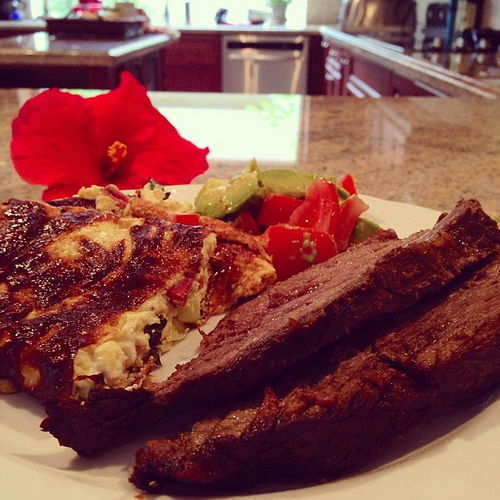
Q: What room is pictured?
A: It is a kitchen.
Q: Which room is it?
A: It is a kitchen.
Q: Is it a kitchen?
A: Yes, it is a kitchen.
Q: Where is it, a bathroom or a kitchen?
A: It is a kitchen.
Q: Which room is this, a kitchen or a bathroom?
A: It is a kitchen.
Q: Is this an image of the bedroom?
A: No, the picture is showing the kitchen.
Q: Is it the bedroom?
A: No, it is the kitchen.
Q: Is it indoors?
A: Yes, it is indoors.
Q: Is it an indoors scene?
A: Yes, it is indoors.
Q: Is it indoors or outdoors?
A: It is indoors.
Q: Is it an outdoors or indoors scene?
A: It is indoors.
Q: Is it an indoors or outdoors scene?
A: It is indoors.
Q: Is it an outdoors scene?
A: No, it is indoors.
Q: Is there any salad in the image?
A: Yes, there is salad.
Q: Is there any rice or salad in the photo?
A: Yes, there is salad.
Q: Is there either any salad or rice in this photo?
A: Yes, there is salad.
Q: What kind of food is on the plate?
A: The food is salad.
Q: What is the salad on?
A: The salad is on the plate.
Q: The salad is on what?
A: The salad is on the plate.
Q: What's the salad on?
A: The salad is on the plate.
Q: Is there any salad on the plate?
A: Yes, there is salad on the plate.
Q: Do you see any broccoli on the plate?
A: No, there is salad on the plate.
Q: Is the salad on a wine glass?
A: No, the salad is on the plate.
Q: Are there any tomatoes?
A: Yes, there is a tomato.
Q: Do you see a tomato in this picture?
A: Yes, there is a tomato.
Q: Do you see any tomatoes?
A: Yes, there is a tomato.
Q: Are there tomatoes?
A: Yes, there is a tomato.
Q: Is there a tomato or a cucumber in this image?
A: Yes, there is a tomato.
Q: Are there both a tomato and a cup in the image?
A: No, there is a tomato but no cups.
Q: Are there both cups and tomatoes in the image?
A: No, there is a tomato but no cups.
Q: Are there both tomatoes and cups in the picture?
A: No, there is a tomato but no cups.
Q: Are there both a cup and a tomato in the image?
A: No, there is a tomato but no cups.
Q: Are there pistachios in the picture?
A: No, there are no pistachios.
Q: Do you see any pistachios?
A: No, there are no pistachios.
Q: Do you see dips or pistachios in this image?
A: No, there are no pistachios or dips.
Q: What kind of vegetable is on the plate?
A: The vegetable is a tomato.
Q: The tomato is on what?
A: The tomato is on the plate.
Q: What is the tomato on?
A: The tomato is on the plate.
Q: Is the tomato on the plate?
A: Yes, the tomato is on the plate.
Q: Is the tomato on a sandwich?
A: No, the tomato is on the plate.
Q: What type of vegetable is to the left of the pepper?
A: The vegetable is a tomato.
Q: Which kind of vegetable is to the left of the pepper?
A: The vegetable is a tomato.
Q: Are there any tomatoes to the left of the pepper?
A: Yes, there is a tomato to the left of the pepper.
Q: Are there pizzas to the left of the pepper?
A: No, there is a tomato to the left of the pepper.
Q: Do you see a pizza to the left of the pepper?
A: No, there is a tomato to the left of the pepper.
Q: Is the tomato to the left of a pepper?
A: Yes, the tomato is to the left of a pepper.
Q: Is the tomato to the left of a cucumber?
A: No, the tomato is to the left of a pepper.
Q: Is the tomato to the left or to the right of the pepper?
A: The tomato is to the left of the pepper.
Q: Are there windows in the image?
A: Yes, there is a window.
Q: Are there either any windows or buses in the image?
A: Yes, there is a window.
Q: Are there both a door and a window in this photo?
A: No, there is a window but no doors.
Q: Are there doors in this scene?
A: No, there are no doors.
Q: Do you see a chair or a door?
A: No, there are no doors or chairs.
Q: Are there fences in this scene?
A: No, there are no fences.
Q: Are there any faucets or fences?
A: No, there are no fences or faucets.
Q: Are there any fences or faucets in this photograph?
A: No, there are no fences or faucets.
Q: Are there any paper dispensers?
A: No, there are no paper dispensers.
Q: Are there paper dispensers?
A: No, there are no paper dispensers.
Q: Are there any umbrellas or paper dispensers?
A: No, there are no paper dispensers or umbrellas.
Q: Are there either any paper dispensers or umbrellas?
A: No, there are no paper dispensers or umbrellas.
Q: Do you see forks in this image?
A: No, there are no forks.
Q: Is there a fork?
A: No, there are no forks.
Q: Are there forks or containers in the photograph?
A: No, there are no forks or containers.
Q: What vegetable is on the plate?
A: The vegetable is an avocado.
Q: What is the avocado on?
A: The avocado is on the plate.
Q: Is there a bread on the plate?
A: No, there is an avocado on the plate.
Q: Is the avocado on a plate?
A: Yes, the avocado is on a plate.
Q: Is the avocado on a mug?
A: No, the avocado is on a plate.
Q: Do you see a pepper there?
A: Yes, there is a pepper.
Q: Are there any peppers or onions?
A: Yes, there is a pepper.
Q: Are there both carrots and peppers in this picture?
A: No, there is a pepper but no carrots.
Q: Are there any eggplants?
A: No, there are no eggplants.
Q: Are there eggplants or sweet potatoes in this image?
A: No, there are no eggplants or sweet potatoes.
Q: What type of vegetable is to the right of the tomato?
A: The vegetable is a pepper.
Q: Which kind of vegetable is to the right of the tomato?
A: The vegetable is a pepper.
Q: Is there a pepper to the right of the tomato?
A: Yes, there is a pepper to the right of the tomato.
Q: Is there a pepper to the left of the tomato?
A: No, the pepper is to the right of the tomato.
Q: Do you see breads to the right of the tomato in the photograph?
A: No, there is a pepper to the right of the tomato.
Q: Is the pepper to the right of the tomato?
A: Yes, the pepper is to the right of the tomato.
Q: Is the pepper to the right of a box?
A: No, the pepper is to the right of the tomato.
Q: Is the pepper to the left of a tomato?
A: No, the pepper is to the right of a tomato.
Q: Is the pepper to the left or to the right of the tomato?
A: The pepper is to the right of the tomato.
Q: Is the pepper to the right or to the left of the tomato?
A: The pepper is to the right of the tomato.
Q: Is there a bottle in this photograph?
A: No, there are no bottles.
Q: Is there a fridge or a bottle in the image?
A: No, there are no bottles or refrigerators.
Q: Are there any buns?
A: No, there are no buns.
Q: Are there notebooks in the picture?
A: No, there are no notebooks.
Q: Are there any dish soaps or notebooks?
A: No, there are no notebooks or dish soaps.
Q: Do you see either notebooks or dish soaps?
A: No, there are no notebooks or dish soaps.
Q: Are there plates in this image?
A: Yes, there is a plate.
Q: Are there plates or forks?
A: Yes, there is a plate.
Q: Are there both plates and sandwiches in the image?
A: No, there is a plate but no sandwiches.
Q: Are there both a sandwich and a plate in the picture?
A: No, there is a plate but no sandwiches.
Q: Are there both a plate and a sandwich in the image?
A: No, there is a plate but no sandwiches.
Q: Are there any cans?
A: No, there are no cans.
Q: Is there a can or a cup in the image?
A: No, there are no cans or cups.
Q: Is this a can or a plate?
A: This is a plate.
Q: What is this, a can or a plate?
A: This is a plate.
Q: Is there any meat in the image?
A: Yes, there is meat.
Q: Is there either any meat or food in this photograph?
A: Yes, there is meat.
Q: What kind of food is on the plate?
A: The food is meat.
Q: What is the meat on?
A: The meat is on the plate.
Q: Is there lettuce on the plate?
A: No, there is meat on the plate.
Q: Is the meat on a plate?
A: Yes, the meat is on a plate.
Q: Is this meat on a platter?
A: No, the meat is on a plate.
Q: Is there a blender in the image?
A: No, there are no blenders.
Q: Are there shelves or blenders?
A: No, there are no blenders or shelves.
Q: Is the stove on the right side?
A: Yes, the stove is on the right of the image.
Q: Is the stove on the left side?
A: No, the stove is on the right of the image.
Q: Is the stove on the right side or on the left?
A: The stove is on the right of the image.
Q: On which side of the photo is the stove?
A: The stove is on the right of the image.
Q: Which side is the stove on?
A: The stove is on the right of the image.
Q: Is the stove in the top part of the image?
A: Yes, the stove is in the top of the image.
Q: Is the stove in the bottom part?
A: No, the stove is in the top of the image.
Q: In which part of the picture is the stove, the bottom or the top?
A: The stove is in the top of the image.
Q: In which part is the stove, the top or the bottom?
A: The stove is in the top of the image.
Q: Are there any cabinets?
A: Yes, there is a cabinet.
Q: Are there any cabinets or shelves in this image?
A: Yes, there is a cabinet.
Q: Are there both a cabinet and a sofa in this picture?
A: No, there is a cabinet but no sofas.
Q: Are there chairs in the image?
A: No, there are no chairs.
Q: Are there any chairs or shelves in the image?
A: No, there are no chairs or shelves.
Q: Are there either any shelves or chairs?
A: No, there are no chairs or shelves.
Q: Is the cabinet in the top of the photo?
A: Yes, the cabinet is in the top of the image.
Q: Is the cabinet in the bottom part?
A: No, the cabinet is in the top of the image.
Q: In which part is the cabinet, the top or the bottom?
A: The cabinet is in the top of the image.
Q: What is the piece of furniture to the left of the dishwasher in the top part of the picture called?
A: The piece of furniture is a cabinet.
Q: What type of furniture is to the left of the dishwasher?
A: The piece of furniture is a cabinet.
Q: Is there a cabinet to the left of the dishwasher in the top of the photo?
A: Yes, there is a cabinet to the left of the dish washer.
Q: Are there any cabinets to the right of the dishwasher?
A: No, the cabinet is to the left of the dishwasher.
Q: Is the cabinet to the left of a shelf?
A: No, the cabinet is to the left of the dish washer.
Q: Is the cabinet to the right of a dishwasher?
A: No, the cabinet is to the left of a dishwasher.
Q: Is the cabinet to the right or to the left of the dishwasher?
A: The cabinet is to the left of the dishwasher.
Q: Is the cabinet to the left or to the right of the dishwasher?
A: The cabinet is to the left of the dishwasher.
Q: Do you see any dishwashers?
A: Yes, there is a dishwasher.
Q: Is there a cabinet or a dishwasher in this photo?
A: Yes, there is a dishwasher.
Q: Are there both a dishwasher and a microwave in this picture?
A: No, there is a dishwasher but no microwaves.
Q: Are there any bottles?
A: No, there are no bottles.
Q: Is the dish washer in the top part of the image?
A: Yes, the dish washer is in the top of the image.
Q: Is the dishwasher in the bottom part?
A: No, the dishwasher is in the top of the image.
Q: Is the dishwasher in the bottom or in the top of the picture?
A: The dishwasher is in the top of the image.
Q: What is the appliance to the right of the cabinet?
A: The appliance is a dishwasher.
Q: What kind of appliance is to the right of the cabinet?
A: The appliance is a dishwasher.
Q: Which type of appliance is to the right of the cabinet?
A: The appliance is a dishwasher.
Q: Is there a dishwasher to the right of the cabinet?
A: Yes, there is a dishwasher to the right of the cabinet.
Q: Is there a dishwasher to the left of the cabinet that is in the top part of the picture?
A: No, the dishwasher is to the right of the cabinet.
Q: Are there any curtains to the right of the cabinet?
A: No, there is a dishwasher to the right of the cabinet.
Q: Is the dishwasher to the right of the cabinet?
A: Yes, the dishwasher is to the right of the cabinet.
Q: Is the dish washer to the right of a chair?
A: No, the dish washer is to the right of the cabinet.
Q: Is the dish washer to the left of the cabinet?
A: No, the dish washer is to the right of the cabinet.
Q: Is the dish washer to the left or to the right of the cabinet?
A: The dish washer is to the right of the cabinet.